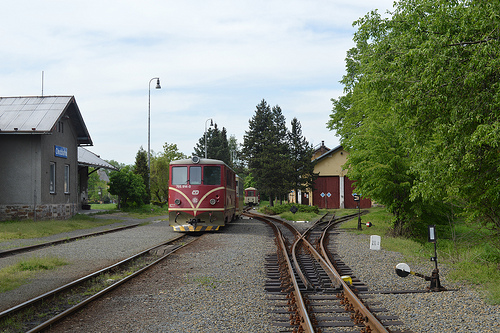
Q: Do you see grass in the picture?
A: Yes, there is grass.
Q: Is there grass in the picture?
A: Yes, there is grass.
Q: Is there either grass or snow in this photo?
A: Yes, there is grass.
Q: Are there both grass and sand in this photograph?
A: No, there is grass but no sand.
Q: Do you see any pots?
A: No, there are no pots.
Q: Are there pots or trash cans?
A: No, there are no pots or trash cans.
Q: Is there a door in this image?
A: Yes, there are doors.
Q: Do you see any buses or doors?
A: Yes, there are doors.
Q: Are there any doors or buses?
A: Yes, there are doors.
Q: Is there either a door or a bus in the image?
A: Yes, there are doors.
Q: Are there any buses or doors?
A: Yes, there are doors.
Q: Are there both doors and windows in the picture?
A: Yes, there are both doors and a window.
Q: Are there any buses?
A: No, there are no buses.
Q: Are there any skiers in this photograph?
A: No, there are no skiers.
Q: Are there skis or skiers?
A: No, there are no skiers or skis.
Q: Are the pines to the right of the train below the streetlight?
A: Yes, the pines are to the right of the train.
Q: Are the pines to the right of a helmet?
A: No, the pines are to the right of the train.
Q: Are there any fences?
A: No, there are no fences.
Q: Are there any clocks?
A: No, there are no clocks.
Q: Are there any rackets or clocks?
A: No, there are no clocks or rackets.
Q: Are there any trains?
A: Yes, there is a train.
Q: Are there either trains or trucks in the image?
A: Yes, there is a train.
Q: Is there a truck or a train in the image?
A: Yes, there is a train.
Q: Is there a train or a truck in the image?
A: Yes, there is a train.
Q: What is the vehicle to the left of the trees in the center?
A: The vehicle is a train.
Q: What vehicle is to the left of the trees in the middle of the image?
A: The vehicle is a train.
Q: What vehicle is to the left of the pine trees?
A: The vehicle is a train.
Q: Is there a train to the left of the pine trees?
A: Yes, there is a train to the left of the pine trees.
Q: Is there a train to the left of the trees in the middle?
A: Yes, there is a train to the left of the pine trees.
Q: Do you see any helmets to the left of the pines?
A: No, there is a train to the left of the pines.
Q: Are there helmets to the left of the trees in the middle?
A: No, there is a train to the left of the pines.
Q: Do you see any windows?
A: Yes, there is a window.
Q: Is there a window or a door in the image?
A: Yes, there is a window.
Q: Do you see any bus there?
A: No, there are no buses.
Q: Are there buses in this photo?
A: No, there are no buses.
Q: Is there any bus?
A: No, there are no buses.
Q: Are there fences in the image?
A: No, there are no fences.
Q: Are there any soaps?
A: No, there are no soaps.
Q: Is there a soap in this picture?
A: No, there are no soaps.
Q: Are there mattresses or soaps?
A: No, there are no soaps or mattresses.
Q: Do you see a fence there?
A: No, there are no fences.